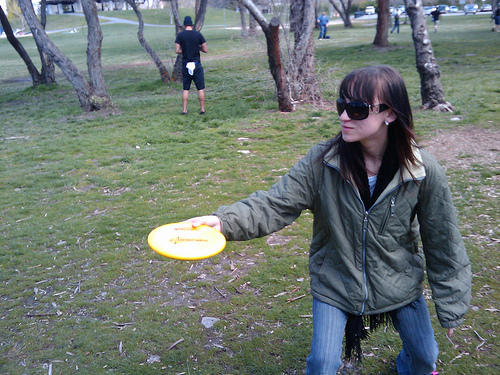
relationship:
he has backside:
[174, 15, 209, 114] [173, 12, 210, 117]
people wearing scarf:
[181, 65, 474, 374] [345, 143, 405, 363]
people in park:
[149, 34, 463, 343] [16, 10, 479, 343]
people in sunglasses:
[181, 65, 474, 374] [333, 99, 388, 120]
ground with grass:
[17, 24, 498, 346] [69, 97, 356, 319]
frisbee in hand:
[141, 190, 240, 275] [169, 193, 243, 255]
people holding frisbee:
[181, 65, 474, 374] [150, 219, 227, 266]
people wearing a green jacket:
[181, 65, 474, 374] [333, 222, 400, 267]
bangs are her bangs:
[339, 67, 379, 106] [334, 70, 381, 103]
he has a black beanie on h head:
[172, 99, 218, 153] [289, 42, 436, 150]